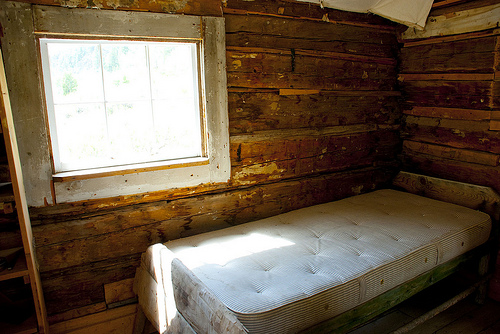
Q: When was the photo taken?
A: Daytime.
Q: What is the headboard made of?
A: Wood.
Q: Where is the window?
A: Wall.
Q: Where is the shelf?
A: Left of the window.